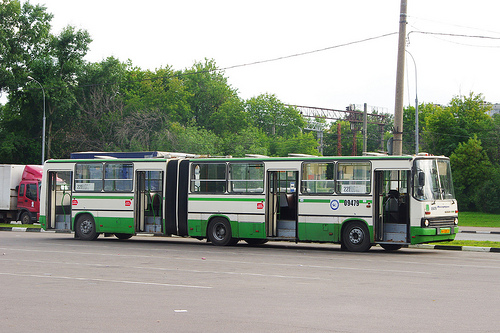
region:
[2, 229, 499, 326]
street is made of asphalt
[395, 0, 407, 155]
wooden telephone pole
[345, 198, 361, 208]
bus number on the side of the bus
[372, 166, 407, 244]
bus door is open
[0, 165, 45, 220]
red and white box truck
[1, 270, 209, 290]
white lines on the street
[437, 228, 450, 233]
orange license plate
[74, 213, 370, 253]
three tires on the passenger side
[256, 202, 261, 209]
red sticker on the bus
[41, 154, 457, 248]
green and white passenger bus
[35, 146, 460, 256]
long green and white bus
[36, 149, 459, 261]
bus has four doors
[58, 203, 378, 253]
bus has 3 sets of wheels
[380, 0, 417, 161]
tall wooden post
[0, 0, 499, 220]
trees in background are green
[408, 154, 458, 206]
windshield of the bus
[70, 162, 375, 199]
windows of the bus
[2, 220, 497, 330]
large gray parking lot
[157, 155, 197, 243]
black rubber connector part of the bus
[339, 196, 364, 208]
ID number on the bus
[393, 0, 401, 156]
brown electricity pole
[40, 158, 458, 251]
green and white bus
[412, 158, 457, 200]
front windows of a bus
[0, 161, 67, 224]
red truck behind a bus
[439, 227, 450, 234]
license plate of a bus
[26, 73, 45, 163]
lamp behind the red truck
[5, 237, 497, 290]
white lines of a parking lot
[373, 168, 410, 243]
open front door of a bus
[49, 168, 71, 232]
open rear door of a bus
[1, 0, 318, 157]
lots of trees behind the bus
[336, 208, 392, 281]
Black tire on bus.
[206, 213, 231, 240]
Black tire on bus.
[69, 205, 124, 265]
Black tire on bus.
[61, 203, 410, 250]
Green section on bottom of bus.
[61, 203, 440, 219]
White section on side of bus.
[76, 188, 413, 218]
Green stripe on side of bus.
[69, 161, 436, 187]
Windows line side of bus.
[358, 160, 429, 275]
Door open near front of bus.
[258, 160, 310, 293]
Door open on side of bus.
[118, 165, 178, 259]
Door open on side of bus.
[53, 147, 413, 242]
double length green bus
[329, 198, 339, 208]
blue circle on bus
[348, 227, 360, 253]
black rubber tire on bus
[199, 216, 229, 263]
black rubber tire on bus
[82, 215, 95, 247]
black rubber tire on bus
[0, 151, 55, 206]
red truck in background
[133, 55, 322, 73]
electric lines over bus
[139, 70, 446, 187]
trees growing behind bus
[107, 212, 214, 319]
white lines on pavement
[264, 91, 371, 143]
metal crane in background